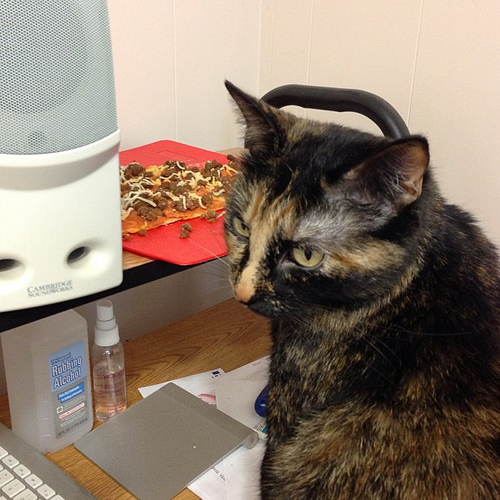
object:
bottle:
[89, 299, 127, 424]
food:
[119, 154, 235, 241]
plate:
[119, 139, 245, 265]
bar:
[260, 83, 413, 139]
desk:
[0, 297, 271, 498]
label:
[47, 339, 90, 439]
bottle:
[0, 308, 99, 451]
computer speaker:
[0, 2, 123, 316]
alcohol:
[0, 308, 94, 456]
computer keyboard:
[0, 448, 63, 499]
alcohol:
[90, 360, 128, 423]